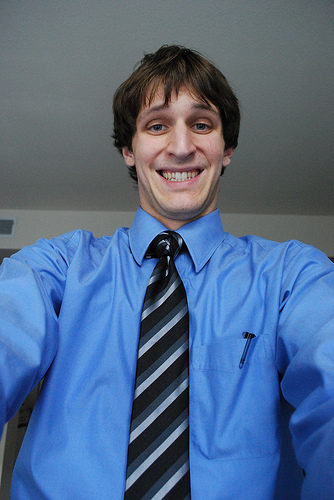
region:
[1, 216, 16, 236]
part of a wall vent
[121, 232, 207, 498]
a man's black and white tie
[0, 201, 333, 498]
part of a man's blue long sleeve shirt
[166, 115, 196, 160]
the nose of a man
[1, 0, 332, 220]
a white ceiling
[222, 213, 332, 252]
part of a white wall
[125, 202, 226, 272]
the collar of a man's shirt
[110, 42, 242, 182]
a man's short cut hair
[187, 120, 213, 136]
the eye of a man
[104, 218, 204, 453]
man wearing a necktie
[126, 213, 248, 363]
man wearing a necktie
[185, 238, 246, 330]
the shirt is blue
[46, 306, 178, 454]
the shirt is blue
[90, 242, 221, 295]
the shirt is blue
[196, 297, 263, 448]
the shirt is blue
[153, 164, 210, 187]
An insincere smile on the man's face.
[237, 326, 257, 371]
A pen hanging from a pocket.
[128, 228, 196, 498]
A black and gray striped tie.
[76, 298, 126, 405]
This shirt is bright blue.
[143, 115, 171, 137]
The eye of the man.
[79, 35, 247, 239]
A man's face, taking his own picture.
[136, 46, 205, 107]
Black hair over his forehead.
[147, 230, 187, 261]
A tie done up in a full knot.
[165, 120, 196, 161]
A large, protruding nose.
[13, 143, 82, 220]
The cieling is white.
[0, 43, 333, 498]
a man in a blue shirt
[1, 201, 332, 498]
a blue dress shirt on the man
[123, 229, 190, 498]
a striped tie on the man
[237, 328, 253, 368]
a pen in the man's pocket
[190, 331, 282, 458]
pocket on the dress shirt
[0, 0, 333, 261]
wall and ceiling behind the man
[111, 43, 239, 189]
shaggy hair on the man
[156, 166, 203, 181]
white teeth of the man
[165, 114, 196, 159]
the man's large nose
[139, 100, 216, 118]
eyebrows of the man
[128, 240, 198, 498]
long striped tie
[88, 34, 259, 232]
man smiling for a picture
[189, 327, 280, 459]
pocket protector with a pen in it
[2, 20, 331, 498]
man wearing a blue shirt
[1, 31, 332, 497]
man wearing a stripped tie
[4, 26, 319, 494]
man wearing a tie and collared shirt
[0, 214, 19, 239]
white framed air vent on wall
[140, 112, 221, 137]
blue eyes of man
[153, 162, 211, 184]
man's teeth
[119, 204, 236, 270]
folded collar of blue shirt